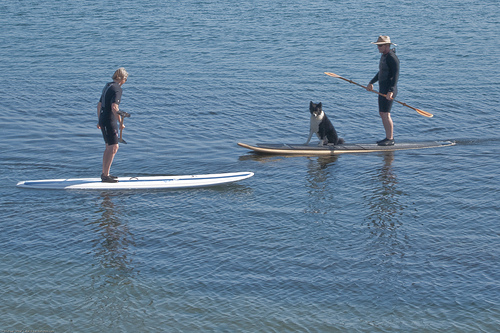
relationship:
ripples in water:
[81, 260, 175, 302] [5, 192, 499, 331]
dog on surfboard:
[304, 99, 351, 151] [235, 132, 464, 156]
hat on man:
[372, 33, 400, 50] [367, 33, 402, 149]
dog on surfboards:
[304, 99, 351, 151] [18, 170, 255, 192]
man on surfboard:
[367, 33, 402, 149] [235, 132, 464, 156]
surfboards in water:
[18, 170, 255, 192] [5, 192, 499, 331]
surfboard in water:
[235, 132, 464, 156] [5, 192, 499, 331]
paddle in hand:
[322, 66, 438, 121] [367, 81, 376, 90]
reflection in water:
[98, 193, 140, 283] [5, 192, 499, 331]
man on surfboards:
[98, 66, 134, 186] [18, 170, 255, 192]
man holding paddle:
[367, 33, 402, 149] [322, 66, 438, 121]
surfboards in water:
[18, 136, 462, 192] [5, 192, 499, 331]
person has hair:
[98, 66, 134, 186] [113, 66, 129, 84]